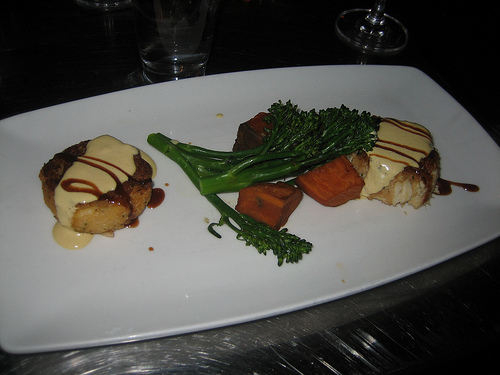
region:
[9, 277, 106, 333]
Small part of white plate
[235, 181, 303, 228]
One piece of carrot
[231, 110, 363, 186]
One piece of broccoli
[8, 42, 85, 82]
Black table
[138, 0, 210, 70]
Glass cup on the left side black table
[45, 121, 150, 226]
Fish cake on the left side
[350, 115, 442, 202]
Fish cake on right side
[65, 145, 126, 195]
White and brown sauce on fish cake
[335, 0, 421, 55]
Glass on right side of black table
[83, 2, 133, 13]
Bottom of glass cup in the back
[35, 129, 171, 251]
sauced poured over meat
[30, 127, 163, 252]
meat buried under sauce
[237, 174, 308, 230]
a cut sweet potato on a plate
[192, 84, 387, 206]
broccoli on top of sweet potatoes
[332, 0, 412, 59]
the stem of a wine glass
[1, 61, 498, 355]
a large white plate holding a meal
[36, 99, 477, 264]
a meal served on a plate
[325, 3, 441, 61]
a wine glass next to a plate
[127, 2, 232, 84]
an empty glass next to a plate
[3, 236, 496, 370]
a plate sitting on a table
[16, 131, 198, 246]
Food on a plate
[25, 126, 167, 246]
Brown food on a white plate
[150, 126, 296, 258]
Green vegetable on a plate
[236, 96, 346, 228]
Orange potatoes on a plate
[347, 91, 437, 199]
Sauce on a food dish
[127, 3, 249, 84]
Glass by a plate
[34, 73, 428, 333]
White plate on a table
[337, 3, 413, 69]
Wine glass by a plate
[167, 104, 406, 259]
Vegetables on a plate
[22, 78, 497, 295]
Dinner on a plate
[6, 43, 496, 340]
a large whiteplate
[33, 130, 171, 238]
meat with a white sauce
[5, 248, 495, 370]
a black table under a plate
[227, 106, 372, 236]
three roasted sweet potatoes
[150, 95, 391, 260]
green broccoli on top of sweet potatoes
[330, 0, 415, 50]
a wine glass on a table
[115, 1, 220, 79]
an empty glass on a table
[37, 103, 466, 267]
a meal on a plate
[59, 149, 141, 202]
dark sauce drizzled on top of meat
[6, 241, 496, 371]
a reflection of a plate on a table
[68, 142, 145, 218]
this is a cake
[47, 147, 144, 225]
the cake is creamy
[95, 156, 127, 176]
the cream is brown in color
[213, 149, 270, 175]
these are veges in the middle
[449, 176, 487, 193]
the cream are flowing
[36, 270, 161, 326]
the plate is white in color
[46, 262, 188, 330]
the plate is flat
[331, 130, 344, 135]
the veges are green in color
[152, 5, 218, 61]
this is a glass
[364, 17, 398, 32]
the glass is shiny